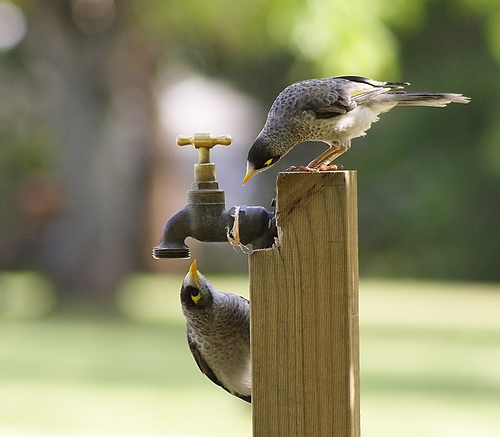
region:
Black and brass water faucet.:
[152, 126, 285, 284]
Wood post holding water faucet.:
[197, 121, 377, 418]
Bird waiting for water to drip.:
[147, 196, 253, 373]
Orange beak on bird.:
[235, 128, 302, 219]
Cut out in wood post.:
[232, 162, 297, 297]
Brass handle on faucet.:
[154, 125, 252, 267]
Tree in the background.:
[49, 28, 183, 315]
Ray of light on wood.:
[330, 343, 362, 430]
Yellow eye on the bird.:
[176, 261, 220, 330]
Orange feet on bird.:
[274, 116, 372, 196]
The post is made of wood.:
[218, 160, 397, 435]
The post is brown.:
[235, 158, 375, 435]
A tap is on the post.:
[130, 103, 301, 265]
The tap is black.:
[152, 195, 309, 269]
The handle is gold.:
[167, 120, 239, 180]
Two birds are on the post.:
[128, 53, 490, 396]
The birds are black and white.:
[138, 65, 482, 402]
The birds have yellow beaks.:
[138, 65, 329, 335]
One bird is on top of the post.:
[233, 56, 473, 199]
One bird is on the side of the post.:
[158, 246, 289, 415]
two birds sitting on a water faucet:
[146, 56, 484, 406]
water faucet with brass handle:
[147, 128, 237, 262]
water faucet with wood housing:
[251, 184, 351, 433]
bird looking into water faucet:
[180, 261, 254, 401]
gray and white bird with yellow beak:
[180, 257, 252, 400]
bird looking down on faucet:
[241, 72, 472, 182]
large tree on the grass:
[28, 35, 150, 321]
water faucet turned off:
[141, 130, 233, 260]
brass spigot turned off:
[153, 135, 239, 263]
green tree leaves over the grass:
[184, 7, 424, 77]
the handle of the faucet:
[172, 133, 238, 184]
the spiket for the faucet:
[137, 235, 196, 269]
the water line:
[237, 201, 284, 259]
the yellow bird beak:
[179, 257, 202, 285]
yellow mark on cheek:
[265, 153, 274, 168]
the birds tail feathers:
[342, 59, 475, 129]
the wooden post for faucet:
[243, 168, 363, 435]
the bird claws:
[279, 162, 315, 173]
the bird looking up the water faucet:
[171, 259, 263, 405]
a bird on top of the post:
[238, 66, 476, 197]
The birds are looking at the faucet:
[107, 70, 434, 419]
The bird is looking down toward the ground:
[231, 88, 395, 200]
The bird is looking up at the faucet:
[173, 260, 259, 415]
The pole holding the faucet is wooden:
[245, 192, 358, 434]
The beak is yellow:
[187, 251, 204, 278]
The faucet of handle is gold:
[173, 137, 232, 192]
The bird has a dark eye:
[187, 285, 201, 302]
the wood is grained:
[270, 250, 347, 405]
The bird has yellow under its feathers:
[330, 80, 395, 103]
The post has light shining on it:
[325, 339, 364, 424]